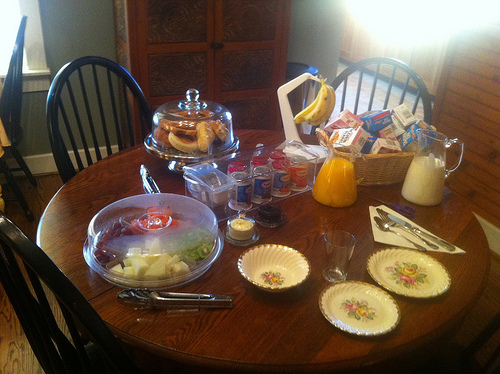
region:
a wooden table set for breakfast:
[37, 125, 487, 365]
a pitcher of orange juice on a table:
[310, 140, 368, 205]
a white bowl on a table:
[237, 243, 307, 289]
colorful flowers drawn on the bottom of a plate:
[341, 295, 376, 323]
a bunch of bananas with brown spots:
[293, 75, 333, 130]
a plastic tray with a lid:
[82, 192, 222, 288]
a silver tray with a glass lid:
[145, 90, 240, 162]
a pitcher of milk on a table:
[402, 127, 463, 203]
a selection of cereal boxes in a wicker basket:
[322, 105, 432, 151]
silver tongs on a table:
[117, 285, 232, 305]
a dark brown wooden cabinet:
[108, 0, 291, 151]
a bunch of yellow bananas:
[293, 80, 335, 126]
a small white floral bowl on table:
[235, 244, 312, 295]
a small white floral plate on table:
[319, 280, 399, 337]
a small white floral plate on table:
[368, 247, 450, 296]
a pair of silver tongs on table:
[116, 288, 231, 309]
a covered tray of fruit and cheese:
[82, 192, 224, 290]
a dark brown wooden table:
[33, 130, 488, 372]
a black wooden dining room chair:
[45, 54, 155, 181]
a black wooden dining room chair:
[0, 218, 137, 372]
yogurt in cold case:
[228, 168, 255, 210]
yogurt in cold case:
[251, 164, 274, 202]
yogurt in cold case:
[273, 156, 293, 196]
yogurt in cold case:
[288, 153, 310, 190]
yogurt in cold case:
[223, 160, 244, 172]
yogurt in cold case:
[271, 147, 282, 160]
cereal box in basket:
[330, 123, 369, 153]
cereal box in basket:
[363, 133, 401, 153]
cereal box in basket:
[356, 108, 393, 129]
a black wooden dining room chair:
[0, 212, 143, 371]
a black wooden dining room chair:
[325, 55, 432, 125]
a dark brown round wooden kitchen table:
[36, 125, 488, 372]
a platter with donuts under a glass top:
[143, 87, 238, 172]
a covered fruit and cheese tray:
[83, 190, 223, 291]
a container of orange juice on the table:
[313, 134, 356, 204]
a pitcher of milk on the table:
[400, 125, 466, 207]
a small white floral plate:
[320, 279, 400, 337]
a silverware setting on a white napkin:
[368, 203, 463, 253]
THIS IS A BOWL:
[230, 235, 318, 303]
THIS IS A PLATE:
[315, 271, 395, 341]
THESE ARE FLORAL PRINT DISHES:
[230, 230, 445, 352]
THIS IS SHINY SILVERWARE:
[370, 201, 456, 261]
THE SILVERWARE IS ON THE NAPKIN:
[357, 202, 462, 268]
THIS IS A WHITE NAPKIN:
[357, 195, 472, 270]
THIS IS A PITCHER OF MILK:
[398, 121, 468, 214]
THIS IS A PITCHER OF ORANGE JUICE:
[318, 135, 375, 223]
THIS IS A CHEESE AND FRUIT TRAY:
[77, 180, 223, 291]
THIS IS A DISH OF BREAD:
[146, 85, 248, 170]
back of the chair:
[26, 33, 162, 176]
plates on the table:
[207, 224, 447, 343]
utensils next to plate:
[362, 195, 461, 261]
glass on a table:
[306, 218, 371, 290]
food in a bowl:
[75, 185, 229, 298]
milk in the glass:
[363, 105, 483, 210]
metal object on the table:
[133, 281, 233, 316]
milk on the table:
[403, 143, 450, 206]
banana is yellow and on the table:
[300, 88, 337, 123]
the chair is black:
[38, 75, 144, 146]